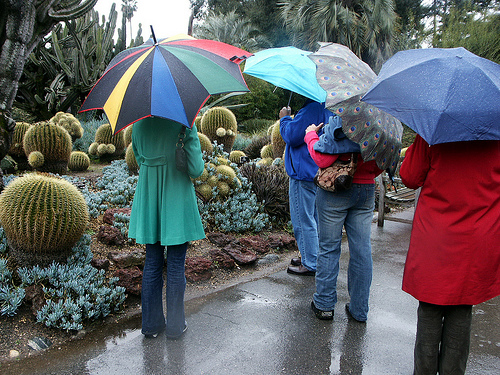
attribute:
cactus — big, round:
[3, 166, 92, 268]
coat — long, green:
[132, 117, 210, 251]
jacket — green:
[123, 119, 205, 244]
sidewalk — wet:
[2, 206, 499, 373]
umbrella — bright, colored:
[76, 31, 255, 137]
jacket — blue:
[261, 97, 341, 177]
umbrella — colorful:
[73, 24, 252, 136]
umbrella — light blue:
[242, 42, 330, 109]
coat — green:
[118, 120, 210, 268]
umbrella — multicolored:
[79, 39, 254, 133]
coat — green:
[128, 117, 204, 246]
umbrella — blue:
[363, 39, 498, 151]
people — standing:
[106, 53, 496, 374]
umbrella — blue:
[355, 46, 487, 148]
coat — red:
[397, 132, 498, 304]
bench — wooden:
[371, 152, 428, 229]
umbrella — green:
[244, 37, 328, 108]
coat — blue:
[277, 99, 329, 188]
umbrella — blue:
[358, 31, 497, 151]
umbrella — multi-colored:
[79, 23, 258, 132]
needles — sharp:
[7, 166, 87, 253]